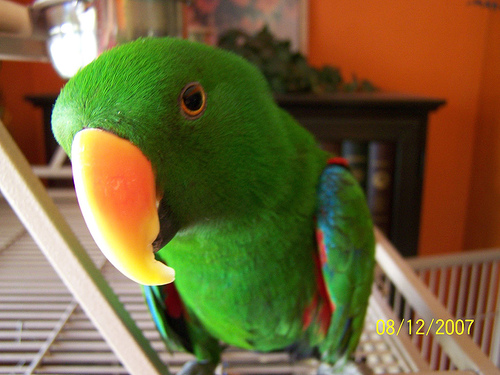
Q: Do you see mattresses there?
A: No, there are no mattresses.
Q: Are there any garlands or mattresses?
A: No, there are no mattresses or garlands.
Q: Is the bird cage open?
A: Yes, the bird cage is open.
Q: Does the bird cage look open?
A: Yes, the bird cage is open.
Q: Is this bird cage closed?
A: No, the bird cage is open.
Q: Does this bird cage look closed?
A: No, the bird cage is open.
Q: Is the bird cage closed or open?
A: The bird cage is open.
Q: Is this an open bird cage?
A: Yes, this is an open bird cage.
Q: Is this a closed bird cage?
A: No, this is an open bird cage.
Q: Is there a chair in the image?
A: No, there are no chairs.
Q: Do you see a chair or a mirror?
A: No, there are no chairs or mirrors.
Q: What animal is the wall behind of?
A: The wall is behind the bird.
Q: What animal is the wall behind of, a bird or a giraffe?
A: The wall is behind a bird.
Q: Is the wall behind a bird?
A: Yes, the wall is behind a bird.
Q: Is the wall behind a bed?
A: No, the wall is behind a bird.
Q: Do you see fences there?
A: No, there are no fences.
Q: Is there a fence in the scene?
A: No, there are no fences.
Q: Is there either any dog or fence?
A: No, there are no fences or dogs.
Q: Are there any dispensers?
A: No, there are no dispensers.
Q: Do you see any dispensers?
A: No, there are no dispensers.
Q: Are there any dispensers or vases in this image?
A: No, there are no dispensers or vases.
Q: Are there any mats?
A: No, there are no mats.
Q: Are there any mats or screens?
A: No, there are no mats or screens.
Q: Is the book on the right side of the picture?
A: Yes, the book is on the right of the image.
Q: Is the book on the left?
A: No, the book is on the right of the image.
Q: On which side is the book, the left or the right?
A: The book is on the right of the image.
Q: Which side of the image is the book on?
A: The book is on the right of the image.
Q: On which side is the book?
A: The book is on the right of the image.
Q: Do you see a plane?
A: No, there are no airplanes.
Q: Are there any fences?
A: No, there are no fences.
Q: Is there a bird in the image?
A: Yes, there is a bird.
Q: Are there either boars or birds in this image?
A: Yes, there is a bird.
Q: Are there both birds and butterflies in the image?
A: No, there is a bird but no butterflies.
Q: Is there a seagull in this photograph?
A: No, there are no seagulls.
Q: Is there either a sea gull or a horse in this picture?
A: No, there are no seagulls or horses.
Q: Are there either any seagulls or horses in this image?
A: No, there are no seagulls or horses.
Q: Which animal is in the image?
A: The animal is a bird.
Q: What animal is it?
A: The animal is a bird.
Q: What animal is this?
A: This is a bird.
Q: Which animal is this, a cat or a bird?
A: This is a bird.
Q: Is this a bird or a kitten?
A: This is a bird.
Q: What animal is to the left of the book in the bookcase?
A: The animal is a bird.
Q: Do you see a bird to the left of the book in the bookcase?
A: Yes, there is a bird to the left of the book.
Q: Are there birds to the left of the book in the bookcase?
A: Yes, there is a bird to the left of the book.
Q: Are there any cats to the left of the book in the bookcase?
A: No, there is a bird to the left of the book.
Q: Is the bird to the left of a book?
A: Yes, the bird is to the left of a book.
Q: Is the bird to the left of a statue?
A: No, the bird is to the left of a book.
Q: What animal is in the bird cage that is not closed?
A: The animal is a bird.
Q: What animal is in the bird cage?
A: The animal is a bird.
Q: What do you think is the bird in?
A: The bird is in the bird cage.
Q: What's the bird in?
A: The bird is in the bird cage.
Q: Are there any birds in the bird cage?
A: Yes, there is a bird in the bird cage.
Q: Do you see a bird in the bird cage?
A: Yes, there is a bird in the bird cage.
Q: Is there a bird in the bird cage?
A: Yes, there is a bird in the bird cage.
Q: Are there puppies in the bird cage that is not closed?
A: No, there is a bird in the bird cage.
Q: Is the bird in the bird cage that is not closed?
A: Yes, the bird is in the bird cage.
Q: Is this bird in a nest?
A: No, the bird is in the bird cage.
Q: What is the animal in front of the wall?
A: The animal is a bird.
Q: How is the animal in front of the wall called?
A: The animal is a bird.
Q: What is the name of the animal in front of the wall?
A: The animal is a bird.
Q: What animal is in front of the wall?
A: The animal is a bird.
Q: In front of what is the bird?
A: The bird is in front of the wall.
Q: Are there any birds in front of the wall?
A: Yes, there is a bird in front of the wall.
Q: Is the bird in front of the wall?
A: Yes, the bird is in front of the wall.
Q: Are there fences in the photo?
A: No, there are no fences.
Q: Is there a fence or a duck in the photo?
A: No, there are no fences or ducks.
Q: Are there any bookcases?
A: Yes, there is a bookcase.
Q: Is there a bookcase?
A: Yes, there is a bookcase.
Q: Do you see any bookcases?
A: Yes, there is a bookcase.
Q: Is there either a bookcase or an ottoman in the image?
A: Yes, there is a bookcase.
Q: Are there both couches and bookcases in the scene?
A: No, there is a bookcase but no couches.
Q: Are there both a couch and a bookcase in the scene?
A: No, there is a bookcase but no couches.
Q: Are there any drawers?
A: No, there are no drawers.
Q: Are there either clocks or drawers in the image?
A: No, there are no drawers or clocks.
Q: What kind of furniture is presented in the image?
A: The furniture is a bookcase.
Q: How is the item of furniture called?
A: The piece of furniture is a bookcase.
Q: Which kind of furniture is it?
A: The piece of furniture is a bookcase.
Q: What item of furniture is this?
A: This is a bookcase.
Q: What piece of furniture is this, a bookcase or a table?
A: This is a bookcase.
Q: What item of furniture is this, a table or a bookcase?
A: This is a bookcase.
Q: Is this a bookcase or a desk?
A: This is a bookcase.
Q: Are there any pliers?
A: No, there are no pliers.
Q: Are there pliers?
A: No, there are no pliers.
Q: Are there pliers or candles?
A: No, there are no pliers or candles.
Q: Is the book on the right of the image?
A: Yes, the book is on the right of the image.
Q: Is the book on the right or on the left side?
A: The book is on the right of the image.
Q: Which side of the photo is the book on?
A: The book is on the right of the image.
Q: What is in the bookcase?
A: The book is in the bookcase.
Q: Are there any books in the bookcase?
A: Yes, there is a book in the bookcase.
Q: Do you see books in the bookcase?
A: Yes, there is a book in the bookcase.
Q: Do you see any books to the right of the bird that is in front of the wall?
A: Yes, there is a book to the right of the bird.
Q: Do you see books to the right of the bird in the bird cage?
A: Yes, there is a book to the right of the bird.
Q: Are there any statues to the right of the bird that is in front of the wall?
A: No, there is a book to the right of the bird.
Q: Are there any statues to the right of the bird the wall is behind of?
A: No, there is a book to the right of the bird.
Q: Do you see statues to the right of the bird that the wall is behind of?
A: No, there is a book to the right of the bird.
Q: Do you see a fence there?
A: No, there are no fences.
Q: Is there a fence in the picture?
A: No, there are no fences.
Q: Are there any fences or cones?
A: No, there are no fences or cones.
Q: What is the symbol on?
A: The symbol is on the book.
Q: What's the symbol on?
A: The symbol is on the book.